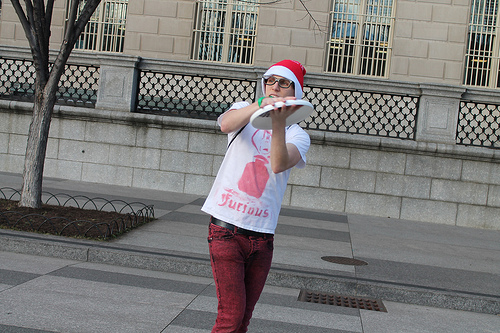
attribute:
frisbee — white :
[246, 94, 374, 139]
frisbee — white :
[247, 99, 316, 135]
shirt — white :
[175, 78, 334, 250]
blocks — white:
[361, 154, 456, 194]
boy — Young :
[207, 58, 312, 331]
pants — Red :
[201, 220, 272, 331]